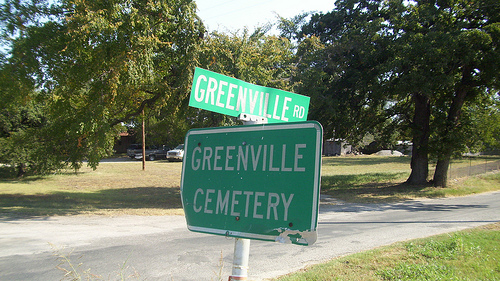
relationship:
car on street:
[145, 148, 165, 160] [84, 156, 410, 170]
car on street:
[167, 141, 182, 158] [84, 156, 410, 170]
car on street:
[132, 148, 142, 158] [84, 156, 410, 170]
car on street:
[134, 147, 170, 161] [1, 3, 494, 276]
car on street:
[167, 143, 185, 162] [1, 3, 494, 276]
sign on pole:
[187, 65, 312, 124] [230, 238, 253, 280]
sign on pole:
[179, 119, 322, 245] [230, 238, 253, 280]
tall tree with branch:
[293, 1, 498, 192] [369, 91, 414, 121]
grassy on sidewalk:
[278, 215, 498, 279] [250, 224, 498, 278]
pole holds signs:
[230, 237, 252, 281] [175, 61, 330, 247]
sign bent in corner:
[179, 127, 313, 249] [176, 189, 201, 228]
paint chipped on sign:
[270, 225, 317, 250] [179, 119, 322, 245]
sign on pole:
[187, 65, 312, 124] [238, 120, 258, 129]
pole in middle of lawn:
[132, 96, 155, 179] [4, 152, 179, 229]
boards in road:
[179, 65, 323, 248] [251, 190, 498, 280]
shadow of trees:
[306, 163, 401, 201] [302, 8, 495, 188]